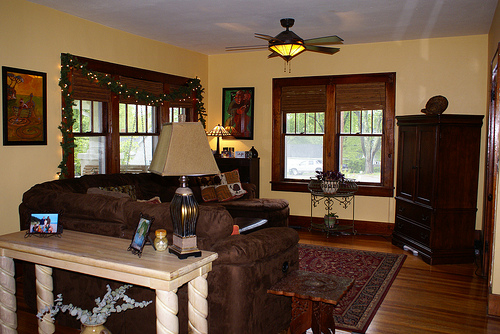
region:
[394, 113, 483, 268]
dark wood cabinet on a wooden floor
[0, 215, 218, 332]
light wood table with spiral designs in the legs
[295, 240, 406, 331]
tan, blue and red Persian style rug on the floor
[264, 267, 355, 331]
dark wooden table next to a dark brown sofa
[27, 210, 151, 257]
two black framed photos on a light table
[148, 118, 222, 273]
gold and tan lamp on a light wood table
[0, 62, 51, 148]
dark framed art work on a cream colored wall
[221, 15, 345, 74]
ceiling fan with light mounted on a white ceiling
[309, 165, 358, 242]
decorative iron plant stand with two plants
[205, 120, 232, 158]
lit lamp in front of framed artwork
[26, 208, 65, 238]
A family picture in a frame.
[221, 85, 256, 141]
A painting on the wall.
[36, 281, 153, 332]
A flower in a vase.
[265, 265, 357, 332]
A brown side table.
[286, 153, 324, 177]
A car outside of window.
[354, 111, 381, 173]
A tree outside of window.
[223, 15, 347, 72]
A ceiling fan with light.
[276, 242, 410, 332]
A nice rug on floor.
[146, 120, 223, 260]
A lamp on table.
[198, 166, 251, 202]
Pillows on the couch.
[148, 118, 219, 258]
A lamp with a tan shade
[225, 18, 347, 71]
A five blade ceiling fan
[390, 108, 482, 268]
A large wooden cabinet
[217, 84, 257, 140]
Framed art on the wall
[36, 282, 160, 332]
A white floral arrangement in a vase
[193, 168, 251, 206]
Pillows on a couch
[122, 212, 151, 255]
A framed picture on the table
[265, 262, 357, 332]
A short wood end table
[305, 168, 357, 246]
A small iron plant stand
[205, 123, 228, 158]
A desk lamp in the corner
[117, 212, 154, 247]
Small family portrait on the wooden table.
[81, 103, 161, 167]
Small family portrait on the wooden table.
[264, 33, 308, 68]
the light is on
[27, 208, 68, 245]
the picture is on the table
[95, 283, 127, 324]
the flowers are white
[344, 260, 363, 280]
the rug is red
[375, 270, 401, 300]
the rug is on the floor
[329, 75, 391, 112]
the blind is open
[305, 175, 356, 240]
the plant stand has two plants on it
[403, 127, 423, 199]
the doors are closed